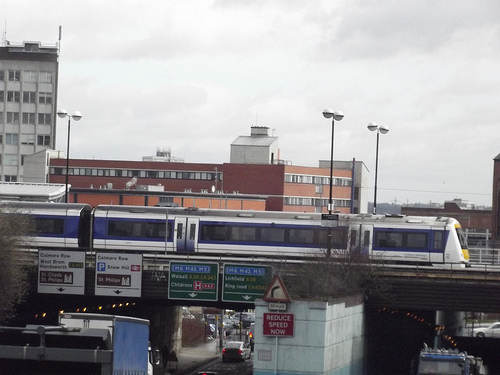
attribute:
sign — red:
[259, 309, 300, 341]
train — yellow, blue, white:
[197, 206, 348, 258]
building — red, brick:
[220, 149, 337, 212]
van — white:
[57, 307, 161, 373]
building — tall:
[1, 41, 58, 197]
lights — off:
[322, 106, 345, 122]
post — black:
[324, 102, 341, 211]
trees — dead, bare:
[292, 246, 378, 304]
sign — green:
[162, 256, 223, 305]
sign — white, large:
[95, 245, 145, 304]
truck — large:
[414, 338, 465, 374]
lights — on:
[222, 346, 242, 359]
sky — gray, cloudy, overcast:
[239, 18, 369, 78]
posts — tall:
[360, 126, 384, 207]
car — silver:
[220, 330, 247, 364]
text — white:
[268, 314, 289, 330]